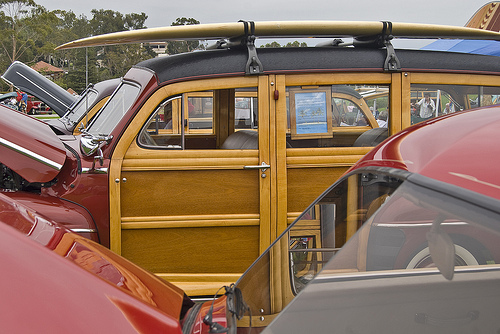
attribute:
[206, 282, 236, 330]
windshield wiper — black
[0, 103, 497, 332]
car — red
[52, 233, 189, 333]
hood — up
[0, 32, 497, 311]
vehicle — antique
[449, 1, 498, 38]
fin — tan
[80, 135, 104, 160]
mirror — side view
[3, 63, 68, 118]
car — raised, black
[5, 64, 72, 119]
hood — black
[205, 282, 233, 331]
wipers — windshield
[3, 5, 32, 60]
tree — tall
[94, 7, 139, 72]
tree — tall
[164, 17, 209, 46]
tree — tall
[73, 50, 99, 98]
tree — tall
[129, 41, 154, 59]
tree — tall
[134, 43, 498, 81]
top — black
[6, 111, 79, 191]
hood — opened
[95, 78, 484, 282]
exterior — wooden